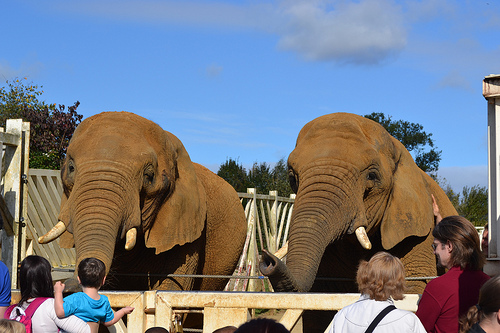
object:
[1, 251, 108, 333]
momma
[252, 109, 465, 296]
elephant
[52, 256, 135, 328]
boy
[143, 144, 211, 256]
ear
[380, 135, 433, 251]
ear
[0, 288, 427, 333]
gate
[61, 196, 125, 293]
trunk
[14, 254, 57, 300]
head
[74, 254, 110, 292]
head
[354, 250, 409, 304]
head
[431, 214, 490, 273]
head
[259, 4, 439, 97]
cloud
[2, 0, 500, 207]
sky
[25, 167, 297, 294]
fence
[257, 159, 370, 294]
trunk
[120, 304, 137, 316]
hand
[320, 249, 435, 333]
person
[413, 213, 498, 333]
person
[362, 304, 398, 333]
strap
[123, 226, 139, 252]
tusk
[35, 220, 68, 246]
tusk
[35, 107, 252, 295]
elephant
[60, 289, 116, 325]
shirt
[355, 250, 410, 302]
hair